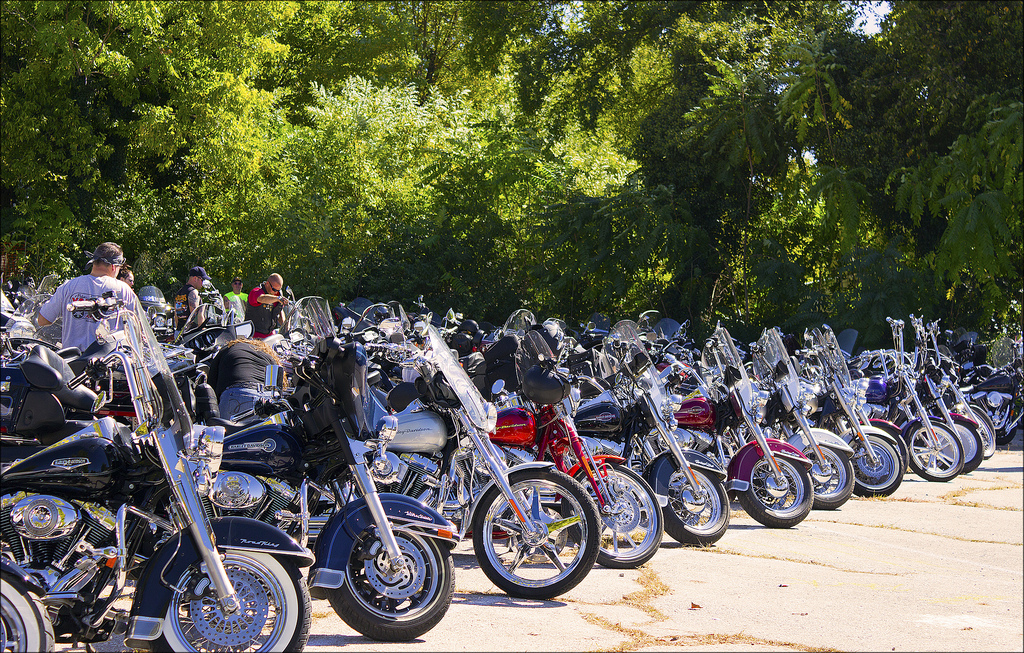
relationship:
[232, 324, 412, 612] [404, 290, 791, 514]
bike in a row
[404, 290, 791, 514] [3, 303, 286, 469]
row of bikes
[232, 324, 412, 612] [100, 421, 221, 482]
bike very shiny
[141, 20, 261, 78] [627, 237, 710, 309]
leaves attached to tree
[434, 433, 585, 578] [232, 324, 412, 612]
wheel attached to bike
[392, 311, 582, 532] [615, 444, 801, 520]
motorcycle has two wheels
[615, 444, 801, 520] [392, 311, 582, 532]
two wheels are on motorcycle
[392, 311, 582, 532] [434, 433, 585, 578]
motorcycle has wheel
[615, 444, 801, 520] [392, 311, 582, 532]
two wheels attached to motorcycle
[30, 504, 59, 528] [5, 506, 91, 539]
emblem on top of gas tank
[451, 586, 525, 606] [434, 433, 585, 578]
shadow under wheel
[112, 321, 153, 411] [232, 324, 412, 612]
windshield on front of bike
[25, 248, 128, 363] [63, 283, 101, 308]
man wearing shirt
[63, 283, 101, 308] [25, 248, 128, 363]
shirt on man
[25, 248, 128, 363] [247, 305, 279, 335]
man wearing vest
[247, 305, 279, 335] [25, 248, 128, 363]
vest on man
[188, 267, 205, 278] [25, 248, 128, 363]
bandana on man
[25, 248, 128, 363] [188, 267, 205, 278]
man wearing bandana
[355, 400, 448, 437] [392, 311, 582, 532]
motor attached to motorcycle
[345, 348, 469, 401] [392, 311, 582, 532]
handlebar of motorcycle